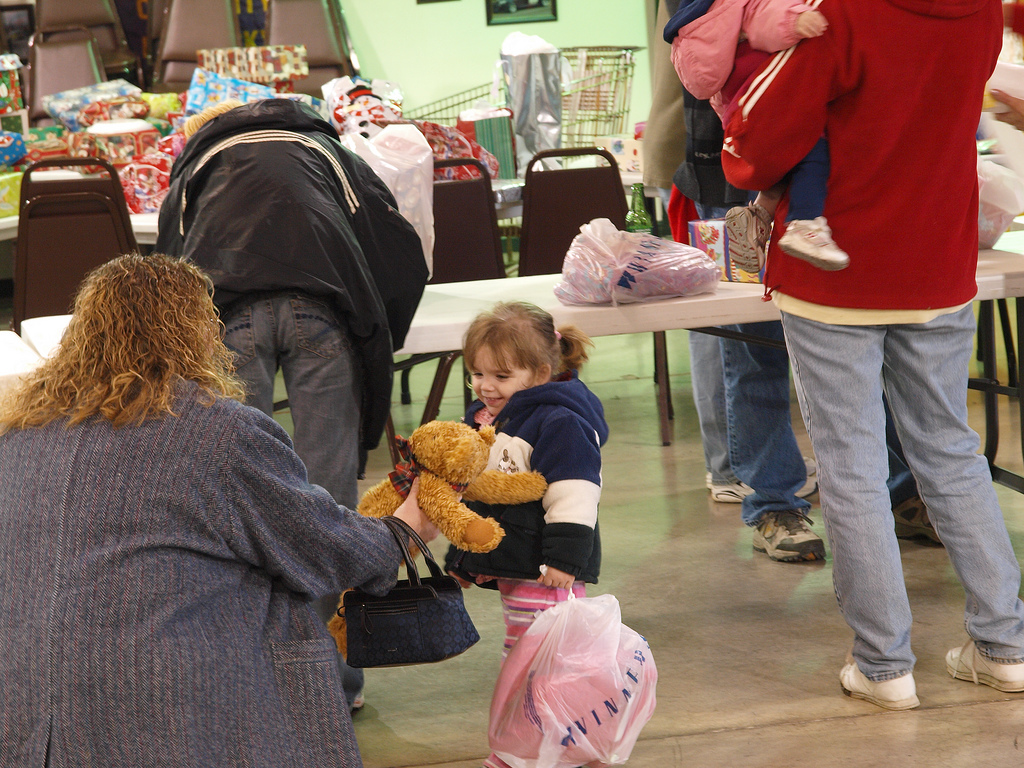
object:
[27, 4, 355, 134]
chairs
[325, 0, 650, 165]
wall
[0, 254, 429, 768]
woman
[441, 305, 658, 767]
girl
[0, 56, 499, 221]
presents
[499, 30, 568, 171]
cart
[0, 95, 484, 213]
table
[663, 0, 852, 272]
baby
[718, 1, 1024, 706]
person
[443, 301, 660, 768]
girl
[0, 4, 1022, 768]
people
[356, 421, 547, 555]
toy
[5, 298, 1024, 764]
ground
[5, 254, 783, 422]
table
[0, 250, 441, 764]
woman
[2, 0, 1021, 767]
building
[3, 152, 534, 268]
table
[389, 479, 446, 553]
hand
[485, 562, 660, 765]
bag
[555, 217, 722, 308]
bag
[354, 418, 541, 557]
teddy bear